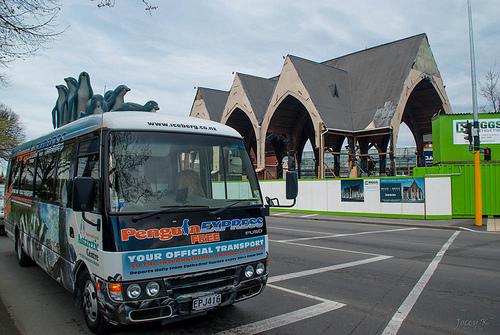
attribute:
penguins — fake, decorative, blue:
[50, 71, 163, 127]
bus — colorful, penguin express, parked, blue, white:
[4, 108, 270, 329]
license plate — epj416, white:
[191, 292, 225, 311]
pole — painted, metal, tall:
[466, 1, 482, 229]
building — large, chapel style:
[188, 32, 450, 173]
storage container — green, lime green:
[412, 111, 498, 214]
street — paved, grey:
[2, 215, 496, 333]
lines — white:
[210, 223, 467, 334]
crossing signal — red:
[484, 146, 493, 165]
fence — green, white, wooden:
[212, 173, 457, 217]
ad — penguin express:
[116, 214, 264, 247]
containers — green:
[412, 114, 498, 216]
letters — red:
[118, 223, 219, 244]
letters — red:
[128, 243, 268, 269]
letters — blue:
[200, 218, 263, 234]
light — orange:
[107, 282, 123, 295]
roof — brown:
[191, 29, 426, 131]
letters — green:
[77, 234, 101, 252]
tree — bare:
[2, 0, 71, 83]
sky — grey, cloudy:
[1, 0, 496, 150]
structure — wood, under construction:
[187, 32, 454, 175]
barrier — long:
[210, 174, 455, 220]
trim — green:
[214, 172, 468, 178]